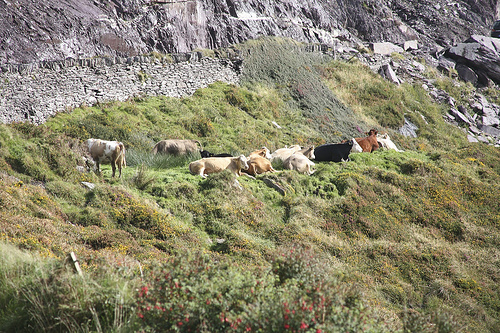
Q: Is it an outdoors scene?
A: Yes, it is outdoors.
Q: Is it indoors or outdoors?
A: It is outdoors.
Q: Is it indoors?
A: No, it is outdoors.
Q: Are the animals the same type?
A: Yes, all the animals are cows.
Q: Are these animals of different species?
A: No, all the animals are cows.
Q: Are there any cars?
A: No, there are no cars.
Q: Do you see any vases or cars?
A: No, there are no cars or vases.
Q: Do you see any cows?
A: Yes, there are cows.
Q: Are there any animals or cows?
A: Yes, there are cows.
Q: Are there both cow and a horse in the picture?
A: No, there are cows but no horses.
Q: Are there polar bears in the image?
A: No, there are no polar bears.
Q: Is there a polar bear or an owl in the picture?
A: No, there are no polar bears or owls.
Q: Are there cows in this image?
A: Yes, there is a cow.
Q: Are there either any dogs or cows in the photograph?
A: Yes, there is a cow.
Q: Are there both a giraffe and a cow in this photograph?
A: No, there is a cow but no giraffes.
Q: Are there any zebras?
A: No, there are no zebras.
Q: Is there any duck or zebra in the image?
A: No, there are no zebras or ducks.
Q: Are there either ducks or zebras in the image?
A: No, there are no zebras or ducks.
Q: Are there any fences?
A: No, there are no fences.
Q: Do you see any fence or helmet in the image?
A: No, there are no fences or helmets.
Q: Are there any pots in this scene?
A: No, there are no pots.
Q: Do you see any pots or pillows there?
A: No, there are no pots or pillows.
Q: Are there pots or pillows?
A: No, there are no pots or pillows.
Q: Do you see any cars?
A: No, there are no cars.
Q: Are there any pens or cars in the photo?
A: No, there are no cars or pens.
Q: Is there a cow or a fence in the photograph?
A: Yes, there is a cow.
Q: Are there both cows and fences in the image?
A: No, there is a cow but no fences.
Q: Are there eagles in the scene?
A: No, there are no eagles.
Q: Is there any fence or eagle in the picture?
A: No, there are no eagles or fences.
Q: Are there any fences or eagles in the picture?
A: No, there are no eagles or fences.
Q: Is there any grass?
A: Yes, there is grass.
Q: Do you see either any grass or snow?
A: Yes, there is grass.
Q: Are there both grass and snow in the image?
A: No, there is grass but no snow.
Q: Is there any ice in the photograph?
A: No, there is no ice.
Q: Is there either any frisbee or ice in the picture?
A: No, there are no ice or frisbees.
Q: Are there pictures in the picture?
A: No, there are no pictures.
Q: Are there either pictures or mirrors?
A: No, there are no pictures or mirrors.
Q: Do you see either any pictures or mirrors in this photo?
A: No, there are no pictures or mirrors.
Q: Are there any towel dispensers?
A: No, there are no towel dispensers.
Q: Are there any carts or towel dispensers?
A: No, there are no towel dispensers or carts.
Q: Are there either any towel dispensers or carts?
A: No, there are no towel dispensers or carts.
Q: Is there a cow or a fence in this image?
A: Yes, there is a cow.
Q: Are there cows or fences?
A: Yes, there is a cow.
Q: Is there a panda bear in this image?
A: No, there are no panda bears.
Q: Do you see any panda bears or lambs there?
A: No, there are no panda bears or lambs.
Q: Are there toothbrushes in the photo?
A: No, there are no toothbrushes.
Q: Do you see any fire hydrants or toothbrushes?
A: No, there are no toothbrushes or fire hydrants.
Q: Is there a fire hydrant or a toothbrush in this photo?
A: No, there are no toothbrushes or fire hydrants.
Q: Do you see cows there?
A: Yes, there is a cow.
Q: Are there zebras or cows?
A: Yes, there is a cow.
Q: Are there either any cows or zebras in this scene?
A: Yes, there is a cow.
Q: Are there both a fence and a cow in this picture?
A: No, there is a cow but no fences.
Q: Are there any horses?
A: No, there are no horses.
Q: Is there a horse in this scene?
A: No, there are no horses.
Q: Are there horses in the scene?
A: No, there are no horses.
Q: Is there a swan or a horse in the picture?
A: No, there are no horses or swans.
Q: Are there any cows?
A: Yes, there is a cow.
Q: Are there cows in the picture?
A: Yes, there is a cow.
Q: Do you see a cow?
A: Yes, there is a cow.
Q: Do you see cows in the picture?
A: Yes, there is a cow.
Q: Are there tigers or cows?
A: Yes, there is a cow.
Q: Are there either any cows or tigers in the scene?
A: Yes, there is a cow.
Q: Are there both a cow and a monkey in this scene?
A: No, there is a cow but no monkeys.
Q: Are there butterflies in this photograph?
A: No, there are no butterflies.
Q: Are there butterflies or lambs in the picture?
A: No, there are no butterflies or lambs.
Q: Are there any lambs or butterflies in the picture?
A: No, there are no butterflies or lambs.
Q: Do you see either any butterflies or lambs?
A: No, there are no butterflies or lambs.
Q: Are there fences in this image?
A: No, there are no fences.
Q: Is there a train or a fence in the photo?
A: No, there are no fences or trains.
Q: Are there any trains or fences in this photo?
A: No, there are no fences or trains.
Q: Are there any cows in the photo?
A: Yes, there is a cow.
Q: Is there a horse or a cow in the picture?
A: Yes, there is a cow.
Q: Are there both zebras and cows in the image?
A: No, there is a cow but no zebras.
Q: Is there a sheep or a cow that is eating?
A: Yes, the cow is eating.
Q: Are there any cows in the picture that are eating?
A: Yes, there is a cow that is eating.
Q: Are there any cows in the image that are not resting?
A: Yes, there is a cow that is eating.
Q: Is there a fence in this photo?
A: No, there are no fences.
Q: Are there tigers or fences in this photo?
A: No, there are no fences or tigers.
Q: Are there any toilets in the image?
A: No, there are no toilets.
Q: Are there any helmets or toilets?
A: No, there are no toilets or helmets.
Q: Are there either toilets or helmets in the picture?
A: No, there are no toilets or helmets.